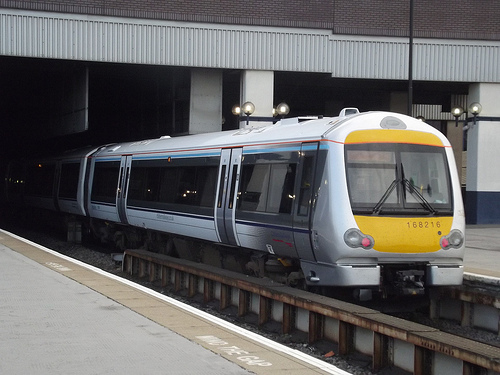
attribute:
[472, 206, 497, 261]
sidewalk — passenger-ready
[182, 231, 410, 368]
barrier — warning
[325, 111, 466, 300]
train front — white, yellow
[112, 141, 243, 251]
doors — silver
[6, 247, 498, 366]
track — rusty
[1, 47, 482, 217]
tunnel — dark 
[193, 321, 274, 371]
writing — white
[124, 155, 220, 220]
window — passenger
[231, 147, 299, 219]
window — passenger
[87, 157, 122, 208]
window — passenger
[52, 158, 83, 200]
window — passenger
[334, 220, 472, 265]
lights — red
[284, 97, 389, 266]
train — yellow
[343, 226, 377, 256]
light — white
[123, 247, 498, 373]
divider — tan, concrete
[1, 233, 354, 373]
platform — cement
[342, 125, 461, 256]
front — yellow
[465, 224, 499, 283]
platform — cement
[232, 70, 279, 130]
pillar — cement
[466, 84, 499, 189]
pillar — cement